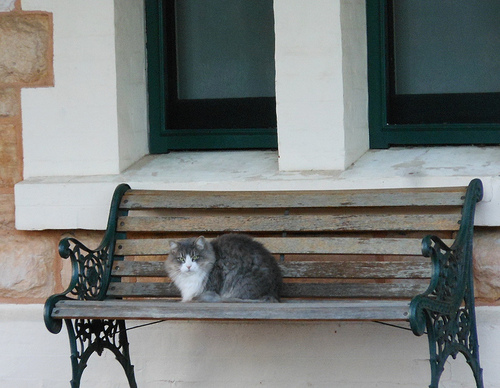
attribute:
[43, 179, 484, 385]
bench — made of wood, wooden, metal, gray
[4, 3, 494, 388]
wall — on the truck, made of wood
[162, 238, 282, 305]
cat — sitting, grey, looking, white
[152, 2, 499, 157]
window — made of wood